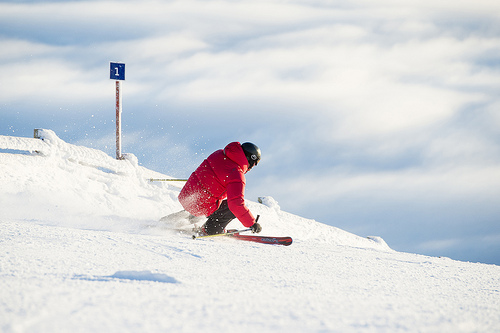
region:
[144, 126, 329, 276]
a man wearing a red ski jacket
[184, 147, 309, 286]
a red ski jacket on a man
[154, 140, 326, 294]
a red ski jacket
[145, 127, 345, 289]
a person skiing on snow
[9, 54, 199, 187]
a post with the number one on it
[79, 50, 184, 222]
a post with a blue number one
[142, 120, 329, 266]
a person skiing with red skis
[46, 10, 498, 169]
a very cloudy day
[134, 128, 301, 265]
a person wearing a black helmet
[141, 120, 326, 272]
a black helmet on a person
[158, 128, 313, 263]
skier is skiing down mountain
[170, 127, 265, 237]
red puffer jacket on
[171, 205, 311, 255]
red skis in the snow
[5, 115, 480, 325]
fresh powder snow on the ground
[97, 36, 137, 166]
blue sign says 1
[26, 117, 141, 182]
several mounds of snow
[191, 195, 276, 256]
black ski pants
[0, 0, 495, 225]
white clouds in blue sky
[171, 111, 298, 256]
skier is hunched over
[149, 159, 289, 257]
ski poles are behind the skier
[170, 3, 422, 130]
A very cloudy sky.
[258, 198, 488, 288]
The edge of the hill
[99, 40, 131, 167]
The number one on a post is a trail marker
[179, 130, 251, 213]
A red hooded parka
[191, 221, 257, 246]
A ski pole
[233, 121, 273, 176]
a black helmet on skier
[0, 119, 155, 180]
A snow covered railing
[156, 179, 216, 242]
snow sprays up behind skier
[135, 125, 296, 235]
Crouching downhill skier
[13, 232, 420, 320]
Tightly packed snow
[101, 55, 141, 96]
Blue square with number 1 in in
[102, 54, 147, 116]
Number 1 is white on blue sign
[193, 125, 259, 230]
Person wearing red coat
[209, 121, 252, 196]
Red coat has hood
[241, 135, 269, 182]
Person wearing dark helmet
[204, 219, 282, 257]
Ski pole in person's hand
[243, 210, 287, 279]
Red and black ski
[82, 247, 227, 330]
Ground is covered in white snow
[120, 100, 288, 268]
Person is skiing down hill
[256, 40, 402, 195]
Blue sky has white clouds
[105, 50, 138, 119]
Blue square on pole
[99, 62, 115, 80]
White number 1 in blue square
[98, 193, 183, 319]
Ground covered in snow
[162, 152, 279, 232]
Person wearing red jacket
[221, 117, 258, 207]
Jacket has puffy hood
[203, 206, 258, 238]
Ski pole in person's hand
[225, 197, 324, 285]
Red and black ski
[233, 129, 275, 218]
Person wearing black helmet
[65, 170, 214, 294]
Person skiing down hill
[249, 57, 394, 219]
White clouds in blue sky